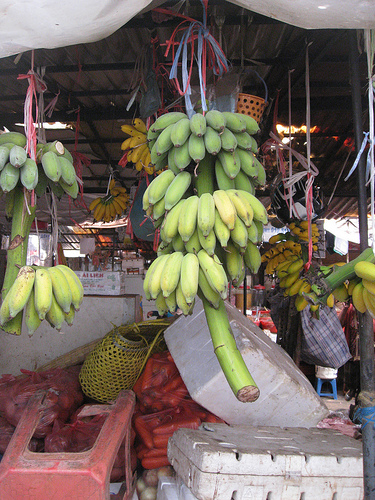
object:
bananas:
[0, 110, 375, 337]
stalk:
[192, 97, 259, 403]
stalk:
[0, 122, 64, 336]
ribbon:
[159, 1, 232, 120]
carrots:
[133, 352, 226, 470]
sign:
[72, 270, 120, 295]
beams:
[349, 31, 374, 500]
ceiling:
[0, 1, 375, 220]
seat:
[314, 365, 337, 400]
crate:
[156, 421, 363, 499]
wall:
[0, 295, 136, 376]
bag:
[4, 366, 83, 439]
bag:
[299, 304, 353, 370]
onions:
[136, 466, 175, 499]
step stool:
[2, 388, 137, 499]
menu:
[261, 220, 321, 277]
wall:
[324, 230, 359, 266]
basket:
[234, 69, 268, 125]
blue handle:
[237, 68, 268, 103]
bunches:
[89, 178, 134, 223]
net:
[0, 0, 375, 63]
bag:
[78, 318, 172, 405]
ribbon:
[266, 37, 318, 272]